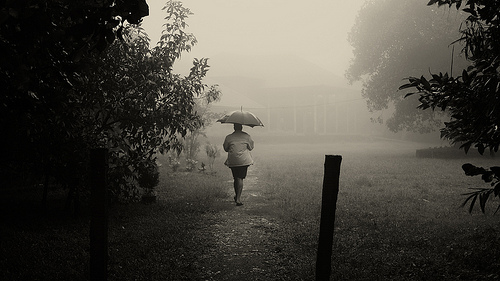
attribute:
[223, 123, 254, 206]
woman — walking, bare legged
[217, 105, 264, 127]
umbrella — white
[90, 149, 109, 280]
post — wooden, here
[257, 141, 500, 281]
grass — here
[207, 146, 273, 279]
path — cobble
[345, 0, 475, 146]
tree — large, here, old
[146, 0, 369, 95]
sky — foggy, misty